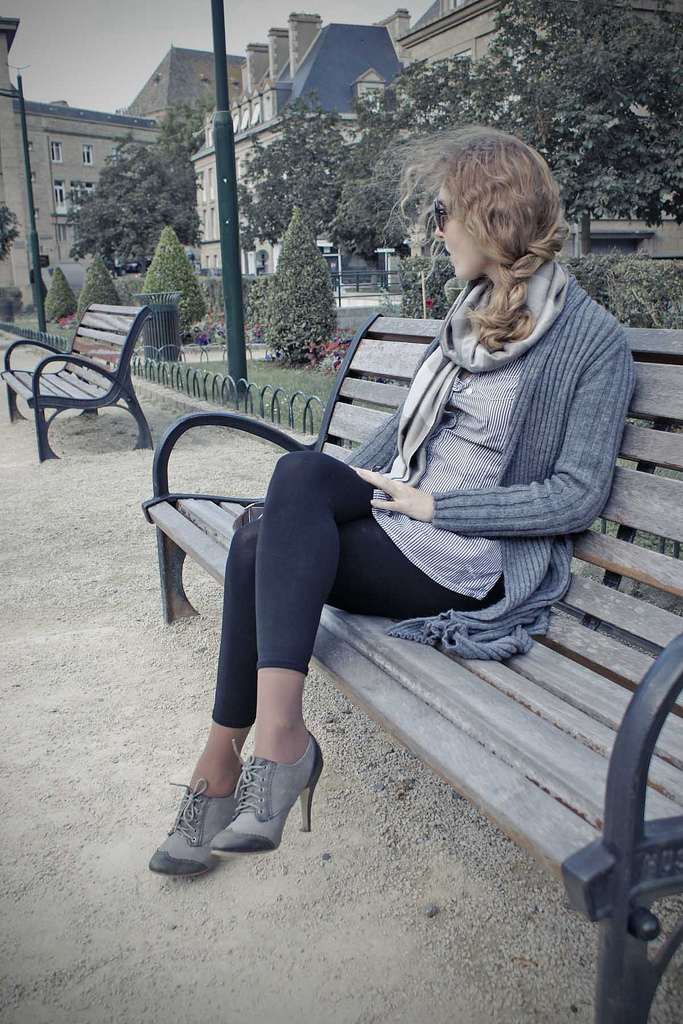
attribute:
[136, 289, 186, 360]
trashcan — black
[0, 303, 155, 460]
bench — empty